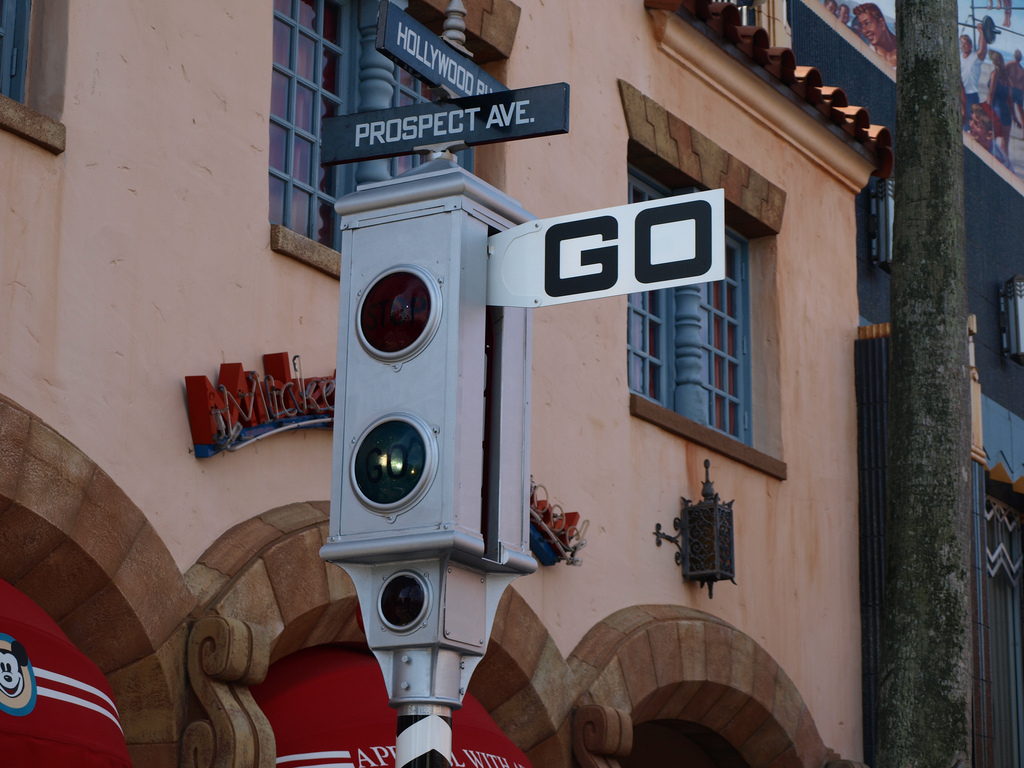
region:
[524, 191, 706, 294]
Black lettering on the sign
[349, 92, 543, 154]
White lettering on the sign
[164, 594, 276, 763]
Cement scroll work on the building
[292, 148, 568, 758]
Traffic signal on the post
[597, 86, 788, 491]
Window in the building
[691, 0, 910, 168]
red clay tile on the roof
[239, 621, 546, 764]
Awning on the building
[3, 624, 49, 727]
Mickey mouse character on the awning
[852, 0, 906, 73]
Man on the sign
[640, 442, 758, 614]
Sconce on the building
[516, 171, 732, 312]
"GO" written on white sign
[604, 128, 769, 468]
A window on a building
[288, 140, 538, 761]
A white traffic light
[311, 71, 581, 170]
"PROSPECT AVE." written on street sign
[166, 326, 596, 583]
A red sign on a building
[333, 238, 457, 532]
Two round lights are not on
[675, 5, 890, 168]
the roof shingles are arched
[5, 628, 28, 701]
the mouse is smiling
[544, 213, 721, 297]
the word go is in black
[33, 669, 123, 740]
the white stripe on the red canopy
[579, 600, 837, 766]
the arches are made of stone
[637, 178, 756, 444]
the window frame is blue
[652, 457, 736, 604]
the black lamp on the building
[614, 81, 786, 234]
the stone trim above the window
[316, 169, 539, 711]
the signal light is silver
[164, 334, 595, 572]
neon red sign on a building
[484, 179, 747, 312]
white sign with black letters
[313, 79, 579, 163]
black sign for prospect ave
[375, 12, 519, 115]
black hollywood blvd sign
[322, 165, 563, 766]
grey sign post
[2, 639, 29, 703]
cartoon image on a red awning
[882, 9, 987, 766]
tall grey tree trunk